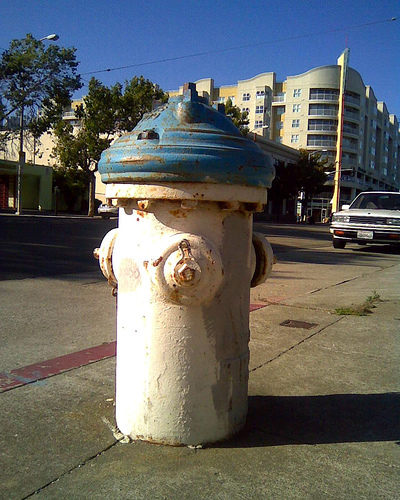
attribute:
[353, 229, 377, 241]
plate — white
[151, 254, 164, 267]
spots — rusty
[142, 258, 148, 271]
spots — rusty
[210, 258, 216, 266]
spots — rusty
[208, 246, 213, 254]
spots — rusty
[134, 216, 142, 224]
spots — rusty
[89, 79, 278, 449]
hydrant — blue-top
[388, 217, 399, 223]
headlight — white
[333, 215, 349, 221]
headlight — white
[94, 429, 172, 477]
paint — white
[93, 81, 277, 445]
fire hydrant — blue, white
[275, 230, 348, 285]
road — side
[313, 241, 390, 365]
plants — small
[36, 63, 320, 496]
hydrant — White , Blue 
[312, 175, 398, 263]
car — white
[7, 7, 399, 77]
sky — blue, clear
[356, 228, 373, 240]
license plate — license 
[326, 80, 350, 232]
curbing — red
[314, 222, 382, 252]
headlight — orange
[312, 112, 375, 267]
truck — parked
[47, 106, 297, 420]
body — yellow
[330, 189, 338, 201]
pillar — pictured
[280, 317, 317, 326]
cover — brown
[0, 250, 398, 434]
sidewalk — dark grey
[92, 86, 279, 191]
top — blue 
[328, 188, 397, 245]
truck — white